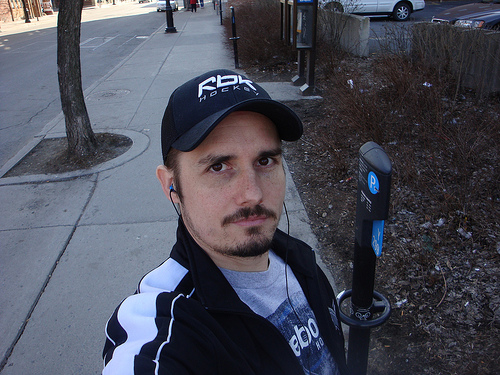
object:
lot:
[319, 5, 493, 71]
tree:
[56, 0, 101, 164]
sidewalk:
[5, 30, 209, 311]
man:
[102, 68, 347, 375]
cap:
[160, 68, 306, 151]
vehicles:
[318, 0, 500, 32]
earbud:
[164, 184, 180, 217]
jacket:
[100, 226, 346, 374]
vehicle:
[320, 0, 425, 22]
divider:
[268, 12, 416, 57]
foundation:
[257, 79, 326, 103]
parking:
[62, 7, 154, 79]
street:
[0, 12, 167, 158]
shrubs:
[364, 41, 462, 136]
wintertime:
[289, 63, 484, 201]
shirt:
[206, 250, 337, 373]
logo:
[287, 316, 327, 356]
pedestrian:
[185, 3, 204, 13]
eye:
[196, 162, 234, 174]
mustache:
[222, 205, 279, 227]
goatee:
[213, 228, 278, 258]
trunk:
[57, 3, 100, 154]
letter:
[195, 73, 266, 96]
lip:
[232, 210, 274, 228]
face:
[177, 124, 288, 257]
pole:
[336, 139, 393, 371]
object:
[364, 170, 381, 195]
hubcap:
[332, 285, 393, 329]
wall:
[318, 12, 382, 54]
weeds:
[326, 62, 426, 126]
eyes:
[196, 155, 281, 173]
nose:
[233, 164, 265, 206]